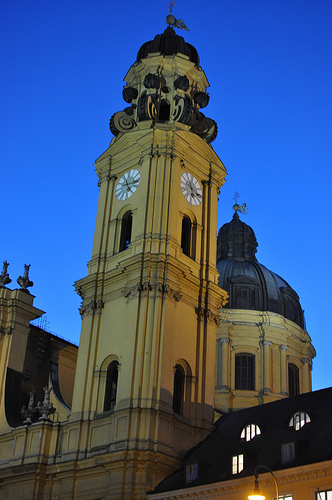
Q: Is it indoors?
A: Yes, it is indoors.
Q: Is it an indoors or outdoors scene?
A: It is indoors.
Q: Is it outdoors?
A: No, it is indoors.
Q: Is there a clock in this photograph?
A: Yes, there is a clock.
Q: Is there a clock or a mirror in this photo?
A: Yes, there is a clock.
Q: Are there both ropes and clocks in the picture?
A: No, there is a clock but no ropes.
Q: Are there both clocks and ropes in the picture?
A: No, there is a clock but no ropes.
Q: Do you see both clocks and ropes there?
A: No, there is a clock but no ropes.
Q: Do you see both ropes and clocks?
A: No, there is a clock but no ropes.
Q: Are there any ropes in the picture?
A: No, there are no ropes.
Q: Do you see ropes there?
A: No, there are no ropes.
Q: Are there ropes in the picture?
A: No, there are no ropes.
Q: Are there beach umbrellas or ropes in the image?
A: No, there are no ropes or beach umbrellas.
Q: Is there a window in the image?
A: Yes, there is a window.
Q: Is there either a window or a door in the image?
A: Yes, there is a window.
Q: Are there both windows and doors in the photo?
A: No, there is a window but no doors.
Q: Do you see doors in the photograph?
A: No, there are no doors.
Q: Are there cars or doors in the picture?
A: No, there are no doors or cars.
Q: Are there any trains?
A: No, there are no trains.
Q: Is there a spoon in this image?
A: No, there are no spoons.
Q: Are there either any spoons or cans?
A: No, there are no spoons or cans.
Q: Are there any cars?
A: No, there are no cars.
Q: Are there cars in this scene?
A: No, there are no cars.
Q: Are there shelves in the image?
A: No, there are no shelves.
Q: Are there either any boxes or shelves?
A: No, there are no shelves or boxes.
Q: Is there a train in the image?
A: No, there are no trains.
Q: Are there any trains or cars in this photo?
A: No, there are no trains or cars.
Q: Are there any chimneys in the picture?
A: No, there are no chimneys.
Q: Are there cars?
A: No, there are no cars.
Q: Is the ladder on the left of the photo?
A: Yes, the ladder is on the left of the image.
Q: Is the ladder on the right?
A: No, the ladder is on the left of the image.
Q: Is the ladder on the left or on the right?
A: The ladder is on the left of the image.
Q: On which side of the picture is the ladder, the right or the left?
A: The ladder is on the left of the image.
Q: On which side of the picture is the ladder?
A: The ladder is on the left of the image.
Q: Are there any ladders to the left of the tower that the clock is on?
A: Yes, there is a ladder to the left of the tower.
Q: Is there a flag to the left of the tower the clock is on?
A: No, there is a ladder to the left of the tower.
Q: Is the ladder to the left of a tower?
A: Yes, the ladder is to the left of a tower.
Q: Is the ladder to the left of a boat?
A: No, the ladder is to the left of a tower.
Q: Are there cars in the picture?
A: No, there are no cars.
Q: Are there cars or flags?
A: No, there are no cars or flags.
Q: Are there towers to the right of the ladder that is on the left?
A: Yes, there is a tower to the right of the ladder.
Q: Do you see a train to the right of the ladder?
A: No, there is a tower to the right of the ladder.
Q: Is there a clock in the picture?
A: Yes, there is a clock.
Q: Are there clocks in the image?
A: Yes, there is a clock.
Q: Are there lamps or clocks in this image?
A: Yes, there is a clock.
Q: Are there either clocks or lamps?
A: Yes, there is a clock.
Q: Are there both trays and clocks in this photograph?
A: No, there is a clock but no trays.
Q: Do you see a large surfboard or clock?
A: Yes, there is a large clock.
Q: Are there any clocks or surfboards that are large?
A: Yes, the clock is large.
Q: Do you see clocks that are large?
A: Yes, there is a large clock.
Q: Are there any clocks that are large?
A: Yes, there is a clock that is large.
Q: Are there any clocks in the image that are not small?
A: Yes, there is a large clock.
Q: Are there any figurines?
A: No, there are no figurines.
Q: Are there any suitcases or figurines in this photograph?
A: No, there are no figurines or suitcases.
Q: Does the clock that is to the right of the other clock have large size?
A: Yes, the clock is large.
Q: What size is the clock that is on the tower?
A: The clock is large.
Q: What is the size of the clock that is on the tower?
A: The clock is large.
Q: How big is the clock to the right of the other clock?
A: The clock is large.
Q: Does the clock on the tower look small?
A: No, the clock is large.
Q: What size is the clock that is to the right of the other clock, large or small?
A: The clock is large.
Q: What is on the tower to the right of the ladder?
A: The clock is on the tower.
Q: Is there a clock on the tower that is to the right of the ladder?
A: Yes, there is a clock on the tower.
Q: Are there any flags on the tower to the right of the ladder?
A: No, there is a clock on the tower.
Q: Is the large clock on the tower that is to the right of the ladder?
A: Yes, the clock is on the tower.